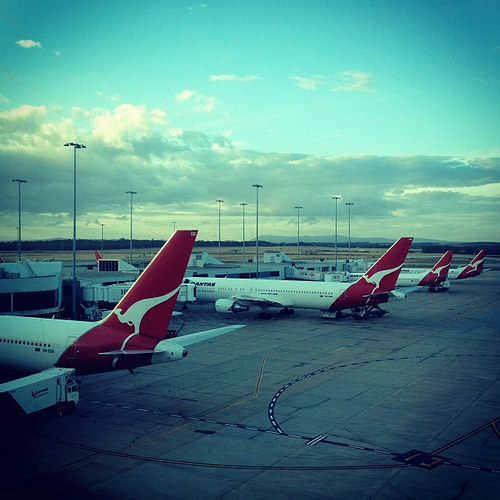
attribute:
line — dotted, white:
[151, 391, 256, 446]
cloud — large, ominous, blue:
[6, 110, 500, 219]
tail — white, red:
[350, 236, 416, 319]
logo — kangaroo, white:
[112, 281, 178, 353]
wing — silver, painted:
[230, 291, 287, 310]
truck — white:
[426, 275, 455, 294]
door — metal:
[64, 336, 78, 361]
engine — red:
[211, 296, 249, 316]